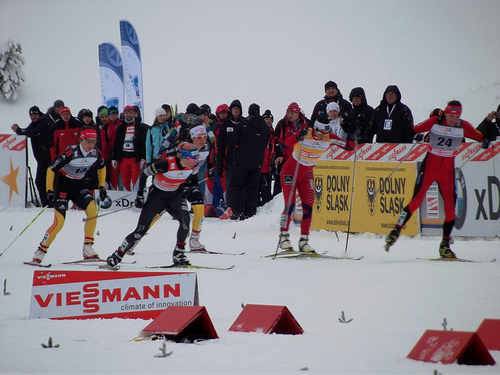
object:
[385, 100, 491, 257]
person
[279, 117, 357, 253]
person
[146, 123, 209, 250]
person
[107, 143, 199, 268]
person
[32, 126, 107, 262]
person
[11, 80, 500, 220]
spectators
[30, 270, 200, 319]
sign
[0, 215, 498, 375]
snow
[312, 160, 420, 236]
sign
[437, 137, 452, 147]
number 24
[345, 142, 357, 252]
ski pole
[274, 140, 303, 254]
ski pole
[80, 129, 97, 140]
headband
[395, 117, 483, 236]
ski suit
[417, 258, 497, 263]
skis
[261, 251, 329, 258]
skis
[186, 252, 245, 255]
skis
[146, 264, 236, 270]
skis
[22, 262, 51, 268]
skis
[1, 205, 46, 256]
ski pole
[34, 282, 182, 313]
lettering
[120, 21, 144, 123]
banner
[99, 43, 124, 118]
banner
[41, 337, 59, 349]
plant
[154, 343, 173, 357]
plant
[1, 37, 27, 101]
tree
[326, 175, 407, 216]
lettering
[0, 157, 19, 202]
star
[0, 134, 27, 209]
sign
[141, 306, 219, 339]
sign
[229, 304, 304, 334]
sign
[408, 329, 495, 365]
sign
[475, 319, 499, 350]
sign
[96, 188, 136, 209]
sign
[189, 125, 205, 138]
headband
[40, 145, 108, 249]
ski suit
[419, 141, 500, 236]
sign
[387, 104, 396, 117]
lanyard